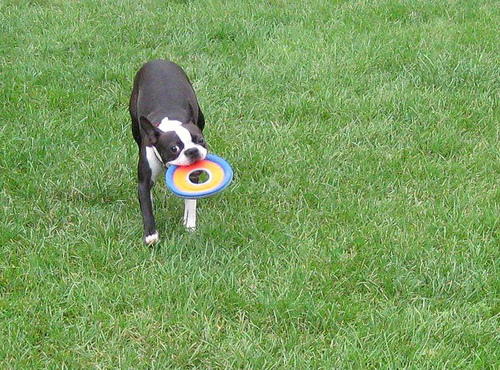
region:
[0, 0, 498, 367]
green lawn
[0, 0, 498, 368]
green grassy lawn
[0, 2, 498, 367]
fresh green grass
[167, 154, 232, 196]
frisbee in dog's mouth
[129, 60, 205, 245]
dog playing on the grass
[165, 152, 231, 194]
colorful frisbee in dog's mouth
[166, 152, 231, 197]
blue, yellow and red frisbee in dog's mouth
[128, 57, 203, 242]
black and white dog carrying frisbee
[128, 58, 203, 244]
cute, small dog playing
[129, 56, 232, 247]
A pug carrying a frisbee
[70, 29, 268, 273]
dog holding frisbee in mouth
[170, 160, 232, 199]
frisbee in dog mouth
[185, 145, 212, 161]
nose of the dog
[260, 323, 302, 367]
patch of green grass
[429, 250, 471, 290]
patch of green grass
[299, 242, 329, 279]
patch of green grass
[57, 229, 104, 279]
patch of green grass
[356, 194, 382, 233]
patch of green grass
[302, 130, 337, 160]
patch of green grass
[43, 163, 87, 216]
patch of green grass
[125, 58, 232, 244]
dog holding a frisbee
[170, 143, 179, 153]
eye of a dog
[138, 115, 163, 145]
ear of a dog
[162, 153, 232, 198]
a blue and orange frisbee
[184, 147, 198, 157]
nose of a dog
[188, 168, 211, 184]
hole in a frisbee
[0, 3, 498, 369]
dog in a field of grass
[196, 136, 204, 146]
eye of a dog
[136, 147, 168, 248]
a dog's front leg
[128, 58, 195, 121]
the back of a dog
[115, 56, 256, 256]
A dog carrying a round disc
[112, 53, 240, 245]
A black and white dog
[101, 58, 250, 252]
A dog standing in the grass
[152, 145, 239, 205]
A blue and orange disc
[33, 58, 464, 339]
Grass and a dog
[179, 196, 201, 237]
A dog with a white leg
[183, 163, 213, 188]
A hole in the center of the disc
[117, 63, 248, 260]
A dog carrying a frisbee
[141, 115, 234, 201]
A frisbee in a dog's mouth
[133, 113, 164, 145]
Black dog ear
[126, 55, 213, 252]
black and white dog carrying frisbee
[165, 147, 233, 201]
blue and orange frisbee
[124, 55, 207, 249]
boston bull dog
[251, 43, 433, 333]
lush green grass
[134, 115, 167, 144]
right ear of black dog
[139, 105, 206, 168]
boston bull dog head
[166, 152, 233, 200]
blue and orange dog toy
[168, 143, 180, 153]
right eye of boston bull dog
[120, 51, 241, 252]
dog playing frisbee on grass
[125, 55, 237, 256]
black and white dog on grass